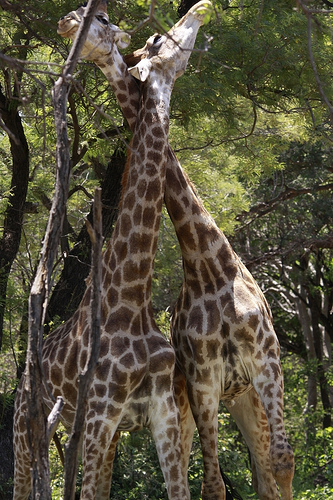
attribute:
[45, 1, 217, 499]
giraffe — looking, brown, white, eating, standing, crossing, growing, tall, reaching, yellow, long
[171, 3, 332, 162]
tree — green, broken